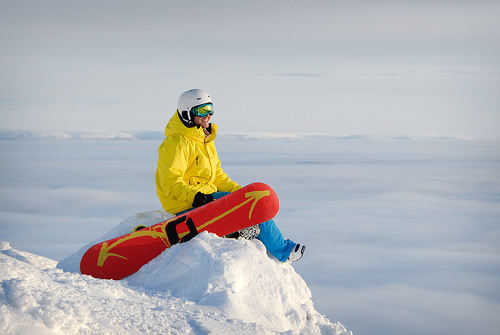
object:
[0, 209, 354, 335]
snow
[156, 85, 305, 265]
person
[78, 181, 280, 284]
snowboard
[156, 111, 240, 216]
jacket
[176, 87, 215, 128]
helmet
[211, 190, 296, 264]
pants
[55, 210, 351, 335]
snow mound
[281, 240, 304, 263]
shoe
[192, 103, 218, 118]
goggles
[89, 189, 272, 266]
design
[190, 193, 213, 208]
glove